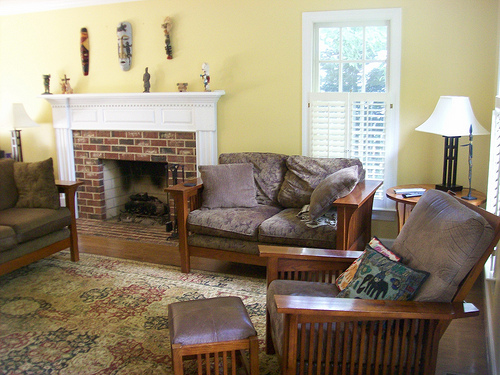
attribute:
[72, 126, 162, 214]
fireplace — brick, unlit, not lit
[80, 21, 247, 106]
wall — above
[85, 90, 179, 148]
mantle — white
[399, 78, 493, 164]
shade — white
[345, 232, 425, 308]
pillow — colorful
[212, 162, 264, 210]
suede — brown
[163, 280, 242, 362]
stool — wooden, wood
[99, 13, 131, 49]
statue — grey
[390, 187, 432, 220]
table — wooden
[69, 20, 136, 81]
decorations — hanging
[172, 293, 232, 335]
ottoman — leather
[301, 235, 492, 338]
recliner — rocking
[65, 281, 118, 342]
rug — ornamental, covering, ornate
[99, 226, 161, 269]
flooring — hardwood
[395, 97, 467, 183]
lamp — black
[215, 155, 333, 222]
couch — two seater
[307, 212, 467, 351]
chair — brown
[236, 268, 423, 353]
seat — love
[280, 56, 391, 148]
window — covered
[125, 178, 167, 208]
wood — burned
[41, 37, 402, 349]
room — living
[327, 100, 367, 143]
shutters — white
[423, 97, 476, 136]
lampshade — white